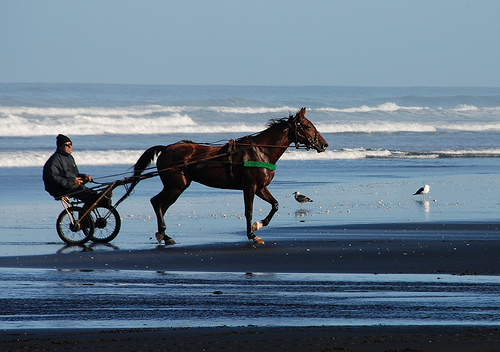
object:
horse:
[126, 105, 329, 247]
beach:
[0, 157, 498, 351]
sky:
[0, 0, 499, 89]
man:
[41, 132, 102, 229]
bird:
[291, 190, 314, 207]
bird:
[412, 183, 432, 197]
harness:
[143, 134, 277, 179]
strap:
[243, 160, 278, 171]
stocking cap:
[55, 133, 73, 148]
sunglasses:
[62, 143, 73, 148]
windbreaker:
[42, 148, 88, 198]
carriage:
[52, 176, 135, 247]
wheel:
[55, 205, 95, 246]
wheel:
[78, 201, 122, 244]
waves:
[0, 146, 161, 167]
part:
[0, 323, 499, 352]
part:
[0, 217, 499, 277]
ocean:
[0, 82, 497, 169]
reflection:
[413, 199, 431, 213]